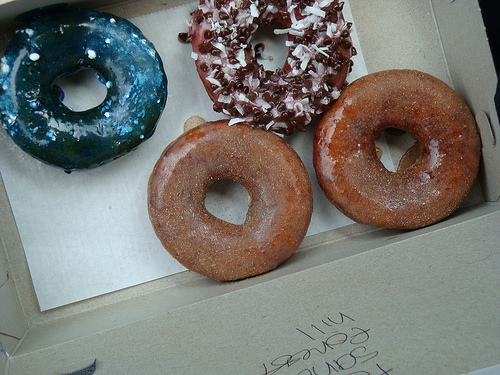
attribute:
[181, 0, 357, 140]
doughnut — dark, brown, large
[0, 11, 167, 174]
doughnut — blue, blueberry glazed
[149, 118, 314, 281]
doughnut — glazed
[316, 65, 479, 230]
doughnut — glazed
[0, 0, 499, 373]
box — open, tan, cardboard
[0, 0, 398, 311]
paper — white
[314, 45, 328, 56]
speck — white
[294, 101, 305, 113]
speck — white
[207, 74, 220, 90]
speck — white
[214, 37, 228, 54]
speck — white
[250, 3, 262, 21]
speck — white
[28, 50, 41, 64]
sprinkle — white, small